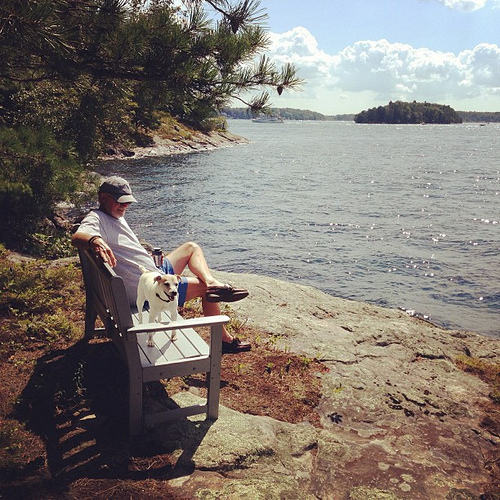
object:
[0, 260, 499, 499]
ground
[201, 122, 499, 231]
water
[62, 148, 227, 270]
harbor area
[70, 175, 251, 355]
man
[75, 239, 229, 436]
bench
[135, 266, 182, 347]
dog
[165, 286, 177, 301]
muzzle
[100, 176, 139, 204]
cap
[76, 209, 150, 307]
t shirt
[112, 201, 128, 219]
face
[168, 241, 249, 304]
leg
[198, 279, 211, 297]
knee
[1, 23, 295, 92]
branch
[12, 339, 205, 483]
shadow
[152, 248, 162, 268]
drink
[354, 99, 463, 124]
island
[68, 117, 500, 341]
lake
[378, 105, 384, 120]
trees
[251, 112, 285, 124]
boat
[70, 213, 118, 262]
arm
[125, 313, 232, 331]
arm rest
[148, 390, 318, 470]
rock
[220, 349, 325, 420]
soil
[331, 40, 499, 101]
cloud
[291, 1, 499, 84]
sky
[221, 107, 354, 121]
hill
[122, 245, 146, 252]
wrinkle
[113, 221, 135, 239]
wrinkle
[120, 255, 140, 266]
wrinkle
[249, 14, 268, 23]
pine needles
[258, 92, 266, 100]
pine needles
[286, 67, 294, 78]
pine needles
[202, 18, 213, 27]
pine needles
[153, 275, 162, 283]
ear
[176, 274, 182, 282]
ear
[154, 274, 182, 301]
face